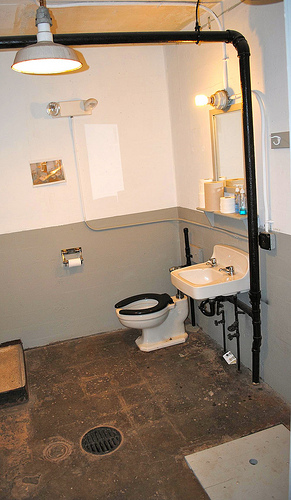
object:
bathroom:
[1, 1, 288, 500]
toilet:
[113, 228, 190, 352]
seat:
[114, 291, 174, 316]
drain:
[77, 426, 123, 458]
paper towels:
[204, 182, 221, 211]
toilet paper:
[67, 259, 81, 267]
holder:
[61, 248, 85, 269]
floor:
[0, 320, 291, 499]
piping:
[0, 29, 262, 385]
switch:
[257, 232, 275, 250]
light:
[193, 93, 211, 108]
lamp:
[10, 0, 84, 75]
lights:
[84, 97, 98, 111]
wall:
[0, 0, 289, 407]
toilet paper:
[218, 197, 234, 213]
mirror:
[215, 113, 243, 179]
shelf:
[197, 203, 249, 221]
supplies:
[198, 178, 206, 208]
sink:
[178, 268, 220, 285]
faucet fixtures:
[219, 265, 235, 275]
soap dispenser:
[239, 208, 247, 215]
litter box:
[0, 339, 27, 405]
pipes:
[237, 300, 253, 319]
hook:
[271, 136, 281, 145]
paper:
[223, 350, 237, 365]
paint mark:
[85, 126, 125, 201]